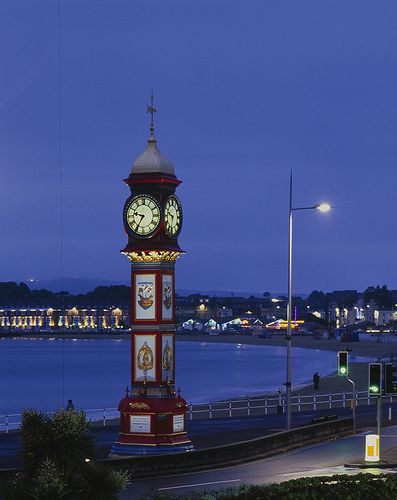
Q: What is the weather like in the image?
A: It is clear.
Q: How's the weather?
A: It is clear.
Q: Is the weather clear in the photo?
A: Yes, it is clear.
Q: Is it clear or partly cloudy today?
A: It is clear.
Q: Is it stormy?
A: No, it is clear.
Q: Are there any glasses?
A: No, there are no glasses.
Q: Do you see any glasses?
A: No, there are no glasses.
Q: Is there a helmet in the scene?
A: No, there are no helmets.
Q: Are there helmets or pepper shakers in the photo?
A: No, there are no helmets or pepper shakers.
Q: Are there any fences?
A: Yes, there is a fence.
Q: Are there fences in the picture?
A: Yes, there is a fence.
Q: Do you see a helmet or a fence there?
A: Yes, there is a fence.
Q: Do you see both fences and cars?
A: No, there is a fence but no cars.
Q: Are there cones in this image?
A: No, there are no cones.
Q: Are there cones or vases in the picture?
A: No, there are no cones or vases.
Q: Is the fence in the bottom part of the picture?
A: Yes, the fence is in the bottom of the image.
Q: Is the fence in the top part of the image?
A: No, the fence is in the bottom of the image.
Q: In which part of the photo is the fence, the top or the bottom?
A: The fence is in the bottom of the image.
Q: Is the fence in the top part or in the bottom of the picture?
A: The fence is in the bottom of the image.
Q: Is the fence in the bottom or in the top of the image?
A: The fence is in the bottom of the image.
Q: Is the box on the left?
A: No, the box is on the right of the image.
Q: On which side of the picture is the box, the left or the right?
A: The box is on the right of the image.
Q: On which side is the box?
A: The box is on the right of the image.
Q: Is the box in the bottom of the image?
A: Yes, the box is in the bottom of the image.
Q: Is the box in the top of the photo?
A: No, the box is in the bottom of the image.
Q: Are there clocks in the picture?
A: Yes, there is a clock.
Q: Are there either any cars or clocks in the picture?
A: Yes, there is a clock.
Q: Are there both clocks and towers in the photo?
A: Yes, there are both a clock and a tower.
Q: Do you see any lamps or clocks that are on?
A: Yes, the clock is on.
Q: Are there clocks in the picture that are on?
A: Yes, there is a clock that is on.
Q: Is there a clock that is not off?
A: Yes, there is a clock that is on.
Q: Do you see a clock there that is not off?
A: Yes, there is a clock that is on .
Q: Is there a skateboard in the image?
A: No, there are no skateboards.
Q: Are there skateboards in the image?
A: No, there are no skateboards.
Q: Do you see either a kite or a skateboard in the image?
A: No, there are no skateboards or kites.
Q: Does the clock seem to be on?
A: Yes, the clock is on.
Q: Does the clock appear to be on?
A: Yes, the clock is on.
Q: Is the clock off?
A: No, the clock is on.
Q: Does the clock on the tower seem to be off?
A: No, the clock is on.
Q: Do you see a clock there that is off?
A: No, there is a clock but it is on.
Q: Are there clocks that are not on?
A: No, there is a clock but it is on.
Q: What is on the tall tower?
A: The clock is on the tower.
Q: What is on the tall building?
A: The clock is on the tower.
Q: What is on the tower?
A: The clock is on the tower.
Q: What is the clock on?
A: The clock is on the tower.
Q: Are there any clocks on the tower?
A: Yes, there is a clock on the tower.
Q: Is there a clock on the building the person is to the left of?
A: Yes, there is a clock on the tower.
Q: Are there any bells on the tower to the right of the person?
A: No, there is a clock on the tower.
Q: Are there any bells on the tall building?
A: No, there is a clock on the tower.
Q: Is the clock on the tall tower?
A: Yes, the clock is on the tower.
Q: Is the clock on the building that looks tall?
A: Yes, the clock is on the tower.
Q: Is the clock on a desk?
A: No, the clock is on the tower.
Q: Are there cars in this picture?
A: No, there are no cars.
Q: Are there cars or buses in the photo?
A: No, there are no cars or buses.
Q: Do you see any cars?
A: No, there are no cars.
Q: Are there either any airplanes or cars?
A: No, there are no cars or airplanes.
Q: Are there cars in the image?
A: No, there are no cars.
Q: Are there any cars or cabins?
A: No, there are no cars or cabins.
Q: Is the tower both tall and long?
A: Yes, the tower is tall and long.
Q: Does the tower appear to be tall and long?
A: Yes, the tower is tall and long.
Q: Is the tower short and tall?
A: No, the tower is tall but long.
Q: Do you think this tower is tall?
A: Yes, the tower is tall.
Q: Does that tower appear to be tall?
A: Yes, the tower is tall.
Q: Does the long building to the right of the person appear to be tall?
A: Yes, the tower is tall.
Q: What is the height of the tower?
A: The tower is tall.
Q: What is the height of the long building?
A: The tower is tall.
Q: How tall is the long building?
A: The tower is tall.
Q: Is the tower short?
A: No, the tower is tall.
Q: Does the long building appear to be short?
A: No, the tower is tall.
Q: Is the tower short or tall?
A: The tower is tall.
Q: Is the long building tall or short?
A: The tower is tall.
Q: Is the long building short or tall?
A: The tower is tall.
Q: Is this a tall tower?
A: Yes, this is a tall tower.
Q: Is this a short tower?
A: No, this is a tall tower.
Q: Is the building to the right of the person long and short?
A: No, the tower is long but tall.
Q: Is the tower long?
A: Yes, the tower is long.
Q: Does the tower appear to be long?
A: Yes, the tower is long.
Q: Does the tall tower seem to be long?
A: Yes, the tower is long.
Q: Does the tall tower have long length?
A: Yes, the tower is long.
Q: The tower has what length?
A: The tower is long.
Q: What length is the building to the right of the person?
A: The tower is long.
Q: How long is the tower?
A: The tower is long.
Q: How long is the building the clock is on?
A: The tower is long.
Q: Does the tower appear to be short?
A: No, the tower is long.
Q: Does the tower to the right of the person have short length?
A: No, the tower is long.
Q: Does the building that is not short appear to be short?
A: No, the tower is long.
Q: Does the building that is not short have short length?
A: No, the tower is long.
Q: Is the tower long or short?
A: The tower is long.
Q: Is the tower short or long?
A: The tower is long.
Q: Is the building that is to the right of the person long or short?
A: The tower is long.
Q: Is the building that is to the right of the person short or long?
A: The tower is long.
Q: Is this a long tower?
A: Yes, this is a long tower.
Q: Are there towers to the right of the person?
A: Yes, there is a tower to the right of the person.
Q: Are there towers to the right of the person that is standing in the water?
A: Yes, there is a tower to the right of the person.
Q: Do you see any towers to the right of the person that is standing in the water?
A: Yes, there is a tower to the right of the person.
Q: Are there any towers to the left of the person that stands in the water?
A: No, the tower is to the right of the person.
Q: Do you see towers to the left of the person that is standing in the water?
A: No, the tower is to the right of the person.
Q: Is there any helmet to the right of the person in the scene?
A: No, there is a tower to the right of the person.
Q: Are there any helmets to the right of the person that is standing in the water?
A: No, there is a tower to the right of the person.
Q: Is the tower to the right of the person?
A: Yes, the tower is to the right of the person.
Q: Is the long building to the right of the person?
A: Yes, the tower is to the right of the person.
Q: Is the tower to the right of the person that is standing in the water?
A: Yes, the tower is to the right of the person.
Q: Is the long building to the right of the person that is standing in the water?
A: Yes, the tower is to the right of the person.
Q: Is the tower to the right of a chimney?
A: No, the tower is to the right of the person.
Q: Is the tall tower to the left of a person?
A: No, the tower is to the right of a person.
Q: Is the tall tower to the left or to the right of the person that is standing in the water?
A: The tower is to the right of the person.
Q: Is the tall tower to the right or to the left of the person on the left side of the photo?
A: The tower is to the right of the person.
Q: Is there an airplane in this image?
A: No, there are no airplanes.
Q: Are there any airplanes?
A: No, there are no airplanes.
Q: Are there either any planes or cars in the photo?
A: No, there are no planes or cars.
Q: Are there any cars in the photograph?
A: No, there are no cars.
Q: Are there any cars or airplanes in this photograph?
A: No, there are no cars or airplanes.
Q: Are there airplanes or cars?
A: No, there are no cars or airplanes.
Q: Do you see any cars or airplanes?
A: No, there are no cars or airplanes.